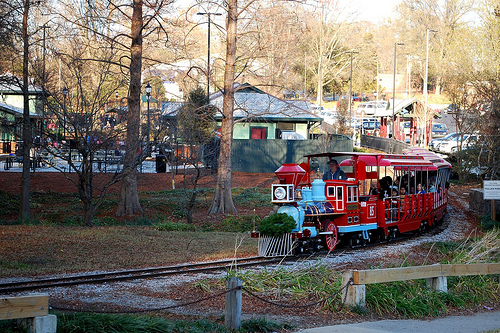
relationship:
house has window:
[160, 82, 325, 141] [275, 119, 295, 133]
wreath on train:
[259, 212, 298, 238] [250, 134, 454, 257]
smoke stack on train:
[275, 163, 306, 189] [250, 134, 454, 257]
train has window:
[250, 134, 454, 257] [346, 185, 358, 203]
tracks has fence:
[0, 253, 297, 293] [339, 263, 500, 305]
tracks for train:
[0, 253, 297, 293] [250, 134, 454, 257]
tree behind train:
[0, 0, 499, 217] [250, 134, 454, 257]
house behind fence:
[160, 82, 325, 141] [202, 133, 355, 172]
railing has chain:
[351, 263, 500, 284] [48, 276, 354, 312]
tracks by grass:
[0, 253, 297, 293] [2, 187, 274, 233]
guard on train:
[320, 160, 347, 183] [250, 134, 454, 257]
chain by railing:
[48, 276, 354, 312] [351, 263, 500, 284]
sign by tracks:
[482, 180, 500, 200] [0, 253, 297, 293]